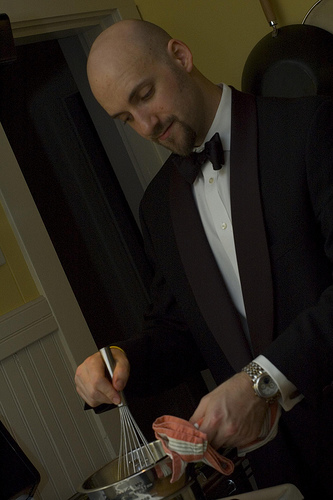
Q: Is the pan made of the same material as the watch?
A: Yes, both the pan and the watch are made of metal.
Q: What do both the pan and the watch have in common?
A: The material, both the pan and the watch are metallic.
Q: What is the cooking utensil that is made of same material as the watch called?
A: The cooking utensil is a pan.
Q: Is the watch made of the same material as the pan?
A: Yes, both the watch and the pan are made of metal.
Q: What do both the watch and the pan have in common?
A: The material, both the watch and the pan are metallic.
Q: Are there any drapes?
A: No, there are no drapes.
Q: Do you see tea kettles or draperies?
A: No, there are no draperies or tea kettles.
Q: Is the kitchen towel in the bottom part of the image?
A: Yes, the kitchen towel is in the bottom of the image.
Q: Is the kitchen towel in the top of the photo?
A: No, the kitchen towel is in the bottom of the image.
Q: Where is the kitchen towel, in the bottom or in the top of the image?
A: The kitchen towel is in the bottom of the image.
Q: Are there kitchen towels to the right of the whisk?
A: Yes, there is a kitchen towel to the right of the whisk.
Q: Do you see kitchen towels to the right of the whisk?
A: Yes, there is a kitchen towel to the right of the whisk.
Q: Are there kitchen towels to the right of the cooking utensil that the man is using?
A: Yes, there is a kitchen towel to the right of the whisk.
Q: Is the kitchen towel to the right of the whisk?
A: Yes, the kitchen towel is to the right of the whisk.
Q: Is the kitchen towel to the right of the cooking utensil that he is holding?
A: Yes, the kitchen towel is to the right of the whisk.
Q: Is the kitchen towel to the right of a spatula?
A: No, the kitchen towel is to the right of the whisk.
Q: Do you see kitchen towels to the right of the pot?
A: Yes, there is a kitchen towel to the right of the pot.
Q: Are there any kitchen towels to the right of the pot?
A: Yes, there is a kitchen towel to the right of the pot.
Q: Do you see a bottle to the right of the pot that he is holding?
A: No, there is a kitchen towel to the right of the pot.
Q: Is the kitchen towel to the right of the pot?
A: Yes, the kitchen towel is to the right of the pot.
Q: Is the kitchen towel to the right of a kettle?
A: No, the kitchen towel is to the right of the pot.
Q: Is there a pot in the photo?
A: Yes, there is a pot.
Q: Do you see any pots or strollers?
A: Yes, there is a pot.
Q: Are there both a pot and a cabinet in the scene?
A: No, there is a pot but no cabinets.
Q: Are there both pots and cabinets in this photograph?
A: No, there is a pot but no cabinets.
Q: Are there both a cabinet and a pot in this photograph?
A: No, there is a pot but no cabinets.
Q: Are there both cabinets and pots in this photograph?
A: No, there is a pot but no cabinets.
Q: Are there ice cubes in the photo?
A: No, there are no ice cubes.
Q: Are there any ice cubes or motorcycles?
A: No, there are no ice cubes or motorcycles.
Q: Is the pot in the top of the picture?
A: No, the pot is in the bottom of the image.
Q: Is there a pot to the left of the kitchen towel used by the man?
A: Yes, there is a pot to the left of the kitchen towel.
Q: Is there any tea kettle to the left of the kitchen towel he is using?
A: No, there is a pot to the left of the kitchen towel.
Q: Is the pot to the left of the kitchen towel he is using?
A: Yes, the pot is to the left of the kitchen towel.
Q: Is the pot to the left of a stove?
A: No, the pot is to the left of the kitchen towel.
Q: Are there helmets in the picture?
A: No, there are no helmets.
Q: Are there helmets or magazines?
A: No, there are no helmets or magazines.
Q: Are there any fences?
A: No, there are no fences.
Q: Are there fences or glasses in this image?
A: No, there are no fences or glasses.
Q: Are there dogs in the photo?
A: No, there are no dogs.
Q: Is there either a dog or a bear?
A: No, there are no dogs or bears.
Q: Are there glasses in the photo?
A: No, there are no glasses.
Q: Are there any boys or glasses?
A: No, there are no glasses or boys.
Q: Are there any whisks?
A: Yes, there is a whisk.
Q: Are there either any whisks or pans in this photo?
A: Yes, there is a whisk.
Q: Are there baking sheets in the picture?
A: No, there are no baking sheets.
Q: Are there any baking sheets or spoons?
A: No, there are no baking sheets or spoons.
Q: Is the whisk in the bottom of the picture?
A: Yes, the whisk is in the bottom of the image.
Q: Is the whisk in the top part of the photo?
A: No, the whisk is in the bottom of the image.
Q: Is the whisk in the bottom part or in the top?
A: The whisk is in the bottom of the image.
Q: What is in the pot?
A: The whisk is in the pot.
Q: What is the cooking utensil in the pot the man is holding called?
A: The cooking utensil is a whisk.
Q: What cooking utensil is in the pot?
A: The cooking utensil is a whisk.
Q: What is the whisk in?
A: The whisk is in the pot.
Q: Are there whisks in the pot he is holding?
A: Yes, there is a whisk in the pot.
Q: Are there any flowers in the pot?
A: No, there is a whisk in the pot.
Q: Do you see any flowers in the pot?
A: No, there is a whisk in the pot.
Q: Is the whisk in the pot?
A: Yes, the whisk is in the pot.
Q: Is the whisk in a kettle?
A: No, the whisk is in the pot.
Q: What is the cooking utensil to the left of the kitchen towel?
A: The cooking utensil is a whisk.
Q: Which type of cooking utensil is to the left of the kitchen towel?
A: The cooking utensil is a whisk.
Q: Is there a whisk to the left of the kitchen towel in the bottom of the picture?
A: Yes, there is a whisk to the left of the kitchen towel.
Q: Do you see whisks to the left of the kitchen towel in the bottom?
A: Yes, there is a whisk to the left of the kitchen towel.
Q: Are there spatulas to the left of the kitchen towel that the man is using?
A: No, there is a whisk to the left of the kitchen towel.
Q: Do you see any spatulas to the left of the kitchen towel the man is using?
A: No, there is a whisk to the left of the kitchen towel.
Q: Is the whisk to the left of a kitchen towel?
A: Yes, the whisk is to the left of a kitchen towel.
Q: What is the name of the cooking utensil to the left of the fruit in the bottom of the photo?
A: The cooking utensil is a whisk.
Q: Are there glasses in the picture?
A: No, there are no glasses.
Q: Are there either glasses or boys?
A: No, there are no glasses or boys.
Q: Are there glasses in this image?
A: No, there are no glasses.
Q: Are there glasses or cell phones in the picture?
A: No, there are no glasses or cell phones.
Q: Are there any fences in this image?
A: No, there are no fences.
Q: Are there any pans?
A: Yes, there is a pan.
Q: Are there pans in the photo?
A: Yes, there is a pan.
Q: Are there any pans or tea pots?
A: Yes, there is a pan.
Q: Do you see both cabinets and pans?
A: No, there is a pan but no cabinets.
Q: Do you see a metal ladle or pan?
A: Yes, there is a metal pan.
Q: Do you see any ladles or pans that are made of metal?
A: Yes, the pan is made of metal.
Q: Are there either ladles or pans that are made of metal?
A: Yes, the pan is made of metal.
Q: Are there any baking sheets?
A: No, there are no baking sheets.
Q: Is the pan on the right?
A: Yes, the pan is on the right of the image.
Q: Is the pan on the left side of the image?
A: No, the pan is on the right of the image.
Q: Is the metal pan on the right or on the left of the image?
A: The pan is on the right of the image.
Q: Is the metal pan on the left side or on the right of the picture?
A: The pan is on the right of the image.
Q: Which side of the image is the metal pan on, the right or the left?
A: The pan is on the right of the image.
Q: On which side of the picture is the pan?
A: The pan is on the right of the image.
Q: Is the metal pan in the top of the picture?
A: Yes, the pan is in the top of the image.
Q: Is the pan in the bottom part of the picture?
A: No, the pan is in the top of the image.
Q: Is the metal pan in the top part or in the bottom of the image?
A: The pan is in the top of the image.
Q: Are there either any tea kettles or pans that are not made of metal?
A: No, there is a pan but it is made of metal.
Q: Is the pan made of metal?
A: Yes, the pan is made of metal.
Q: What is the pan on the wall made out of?
A: The pan is made of metal.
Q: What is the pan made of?
A: The pan is made of metal.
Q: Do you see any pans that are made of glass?
A: No, there is a pan but it is made of metal.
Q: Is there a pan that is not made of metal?
A: No, there is a pan but it is made of metal.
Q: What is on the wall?
A: The pan is on the wall.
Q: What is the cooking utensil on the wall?
A: The cooking utensil is a pan.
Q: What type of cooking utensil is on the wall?
A: The cooking utensil is a pan.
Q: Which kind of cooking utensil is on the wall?
A: The cooking utensil is a pan.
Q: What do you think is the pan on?
A: The pan is on the wall.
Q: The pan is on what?
A: The pan is on the wall.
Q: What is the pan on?
A: The pan is on the wall.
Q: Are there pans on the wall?
A: Yes, there is a pan on the wall.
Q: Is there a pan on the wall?
A: Yes, there is a pan on the wall.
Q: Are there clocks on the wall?
A: No, there is a pan on the wall.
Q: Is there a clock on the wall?
A: No, there is a pan on the wall.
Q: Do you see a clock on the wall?
A: No, there is a pan on the wall.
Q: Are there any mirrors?
A: No, there are no mirrors.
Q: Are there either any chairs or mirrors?
A: No, there are no mirrors or chairs.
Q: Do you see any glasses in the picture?
A: No, there are no glasses.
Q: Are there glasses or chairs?
A: No, there are no glasses or chairs.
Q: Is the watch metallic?
A: Yes, the watch is metallic.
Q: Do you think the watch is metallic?
A: Yes, the watch is metallic.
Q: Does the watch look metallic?
A: Yes, the watch is metallic.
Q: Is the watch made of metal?
A: Yes, the watch is made of metal.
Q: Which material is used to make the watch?
A: The watch is made of metal.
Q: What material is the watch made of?
A: The watch is made of metal.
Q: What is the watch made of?
A: The watch is made of metal.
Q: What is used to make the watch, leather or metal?
A: The watch is made of metal.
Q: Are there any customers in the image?
A: No, there are no customers.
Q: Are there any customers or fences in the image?
A: No, there are no customers or fences.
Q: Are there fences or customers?
A: No, there are no customers or fences.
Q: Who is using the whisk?
A: The man is using the whisk.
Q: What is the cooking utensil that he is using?
A: The cooking utensil is a whisk.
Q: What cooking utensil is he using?
A: The man is using a whisk.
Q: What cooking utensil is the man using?
A: The man is using a whisk.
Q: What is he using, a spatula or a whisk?
A: The man is using a whisk.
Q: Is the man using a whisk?
A: Yes, the man is using a whisk.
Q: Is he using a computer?
A: No, the man is using a whisk.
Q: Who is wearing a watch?
A: The man is wearing a watch.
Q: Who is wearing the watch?
A: The man is wearing a watch.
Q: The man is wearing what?
A: The man is wearing a watch.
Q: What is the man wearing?
A: The man is wearing a watch.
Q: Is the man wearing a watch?
A: Yes, the man is wearing a watch.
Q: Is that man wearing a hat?
A: No, the man is wearing a watch.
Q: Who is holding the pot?
A: The man is holding the pot.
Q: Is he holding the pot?
A: Yes, the man is holding the pot.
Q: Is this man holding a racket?
A: No, the man is holding the pot.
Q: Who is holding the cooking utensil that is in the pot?
A: The man is holding the whisk.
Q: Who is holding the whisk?
A: The man is holding the whisk.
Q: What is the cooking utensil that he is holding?
A: The cooking utensil is a whisk.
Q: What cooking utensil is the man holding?
A: The man is holding the whisk.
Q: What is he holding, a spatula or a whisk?
A: The man is holding a whisk.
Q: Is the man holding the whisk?
A: Yes, the man is holding the whisk.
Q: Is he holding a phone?
A: No, the man is holding the whisk.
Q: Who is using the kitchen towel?
A: The man is using the kitchen towel.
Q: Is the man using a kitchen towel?
A: Yes, the man is using a kitchen towel.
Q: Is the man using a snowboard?
A: No, the man is using a kitchen towel.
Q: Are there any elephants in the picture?
A: No, there are no elephants.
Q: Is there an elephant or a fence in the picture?
A: No, there are no elephants or fences.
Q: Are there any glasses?
A: No, there are no glasses.